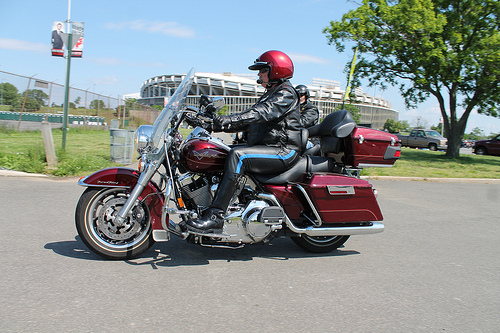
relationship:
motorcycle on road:
[73, 66, 404, 264] [0, 173, 499, 332]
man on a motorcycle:
[182, 49, 304, 237] [73, 66, 404, 264]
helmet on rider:
[253, 49, 295, 83] [182, 49, 304, 237]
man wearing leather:
[182, 49, 304, 237] [215, 80, 304, 178]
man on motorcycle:
[182, 49, 304, 237] [73, 66, 404, 264]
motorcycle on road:
[70, 64, 392, 263] [0, 173, 499, 332]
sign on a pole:
[48, 18, 86, 60] [60, 0, 73, 151]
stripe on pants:
[234, 148, 296, 175] [224, 143, 302, 178]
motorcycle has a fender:
[73, 66, 404, 264] [76, 165, 171, 244]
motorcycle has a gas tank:
[73, 66, 404, 264] [178, 135, 234, 177]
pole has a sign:
[60, 0, 73, 151] [48, 18, 86, 60]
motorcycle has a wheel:
[73, 66, 404, 264] [73, 174, 162, 264]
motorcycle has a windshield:
[73, 66, 404, 264] [150, 64, 197, 151]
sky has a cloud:
[0, 0, 499, 138] [0, 18, 333, 69]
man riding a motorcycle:
[182, 49, 304, 237] [73, 66, 404, 264]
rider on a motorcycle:
[182, 49, 304, 237] [73, 66, 404, 264]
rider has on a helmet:
[182, 49, 304, 237] [253, 49, 295, 83]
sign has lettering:
[48, 18, 86, 60] [68, 23, 85, 33]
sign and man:
[48, 18, 86, 60] [50, 21, 65, 51]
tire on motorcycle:
[291, 224, 351, 254] [73, 66, 404, 264]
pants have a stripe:
[224, 143, 302, 178] [234, 148, 296, 175]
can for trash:
[108, 126, 138, 167] [109, 152, 134, 166]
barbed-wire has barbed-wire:
[0, 68, 155, 128] [0, 64, 161, 109]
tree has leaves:
[321, 0, 499, 161] [320, 0, 499, 122]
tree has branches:
[321, 0, 499, 161] [427, 82, 483, 130]